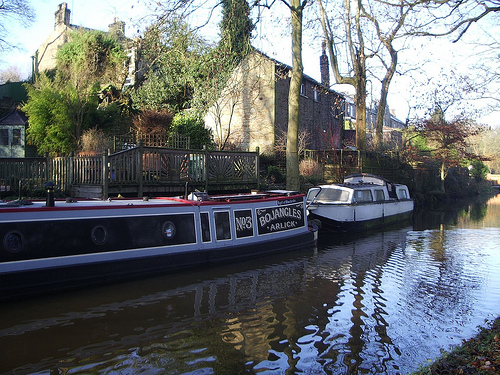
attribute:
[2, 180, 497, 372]
water — calm, murky, rippling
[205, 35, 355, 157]
house — brick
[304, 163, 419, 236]
boat — white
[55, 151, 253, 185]
fence — wooden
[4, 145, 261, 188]
railing — wooden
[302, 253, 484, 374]
water — murky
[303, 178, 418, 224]
boat — small, white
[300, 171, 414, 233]
boat — small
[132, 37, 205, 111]
leaves — green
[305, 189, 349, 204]
windshield — dirty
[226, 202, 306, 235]
name — company's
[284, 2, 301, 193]
tree trunk — tall